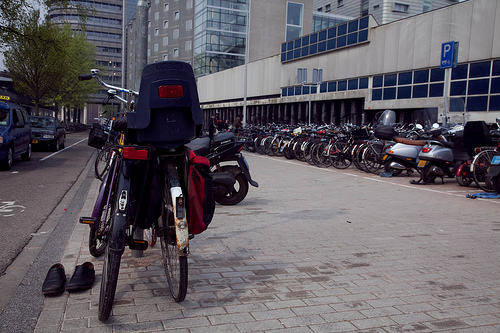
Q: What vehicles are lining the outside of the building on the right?
A: Motorcycles.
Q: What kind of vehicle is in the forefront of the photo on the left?
A: Bicycle.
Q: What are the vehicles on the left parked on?
A: Sidewalk.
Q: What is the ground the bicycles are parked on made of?
A: Bricks.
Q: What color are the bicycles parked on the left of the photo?
A: Black and red.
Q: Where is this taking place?
A: Outside the hotel.